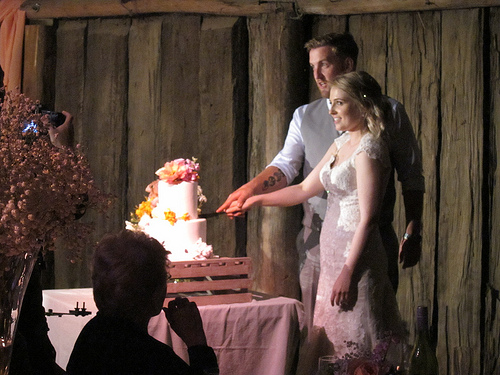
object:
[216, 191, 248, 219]
hand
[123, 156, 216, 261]
flower decorations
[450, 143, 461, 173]
ground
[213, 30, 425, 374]
man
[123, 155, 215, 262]
cake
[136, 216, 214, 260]
tier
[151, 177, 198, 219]
tier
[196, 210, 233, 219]
knife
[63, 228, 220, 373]
person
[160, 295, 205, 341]
hand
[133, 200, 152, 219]
yellow flowers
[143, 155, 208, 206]
pink flowers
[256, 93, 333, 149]
wall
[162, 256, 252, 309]
crate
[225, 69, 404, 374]
bride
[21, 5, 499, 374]
fence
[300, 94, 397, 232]
vest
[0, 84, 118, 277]
flower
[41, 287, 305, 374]
cloth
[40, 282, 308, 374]
table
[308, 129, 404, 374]
dress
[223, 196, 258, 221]
hand